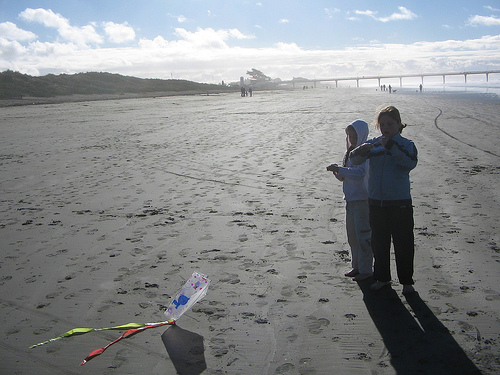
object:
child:
[325, 118, 374, 282]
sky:
[1, 3, 497, 79]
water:
[399, 81, 499, 94]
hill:
[0, 68, 228, 99]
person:
[248, 88, 252, 96]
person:
[418, 82, 423, 91]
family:
[248, 88, 253, 98]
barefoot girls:
[347, 105, 419, 296]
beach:
[0, 89, 498, 374]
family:
[324, 119, 374, 282]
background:
[0, 0, 499, 132]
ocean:
[343, 79, 500, 92]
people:
[247, 87, 252, 97]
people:
[380, 85, 383, 91]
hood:
[346, 119, 370, 146]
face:
[379, 114, 398, 138]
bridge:
[278, 68, 500, 91]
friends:
[388, 84, 392, 94]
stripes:
[374, 141, 381, 145]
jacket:
[347, 131, 419, 202]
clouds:
[0, 7, 500, 71]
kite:
[28, 269, 214, 367]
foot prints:
[331, 337, 341, 343]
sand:
[0, 87, 497, 374]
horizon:
[0, 84, 500, 110]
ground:
[1, 80, 498, 375]